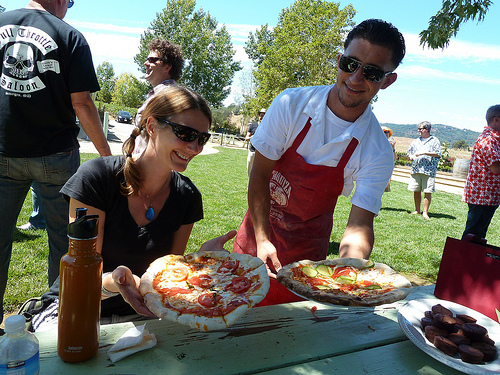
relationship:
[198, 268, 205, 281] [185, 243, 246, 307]
tomato on pizza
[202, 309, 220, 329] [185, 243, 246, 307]
crust of pizza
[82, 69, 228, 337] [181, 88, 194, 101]
woman with hair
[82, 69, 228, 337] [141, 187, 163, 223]
woman has blue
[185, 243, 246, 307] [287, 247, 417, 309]
pizza by pizza